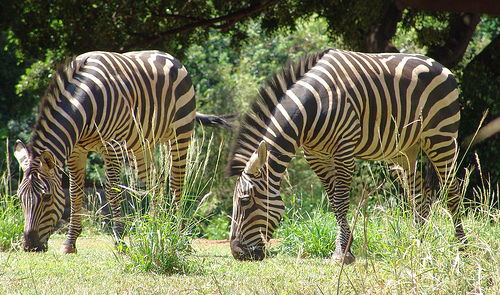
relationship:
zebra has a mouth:
[13, 48, 197, 255] [25, 241, 46, 252]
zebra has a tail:
[13, 48, 197, 255] [196, 111, 239, 129]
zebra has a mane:
[13, 48, 197, 255] [29, 52, 87, 164]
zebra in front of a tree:
[13, 48, 197, 255] [112, 3, 499, 211]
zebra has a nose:
[13, 48, 197, 255] [231, 238, 244, 259]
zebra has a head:
[13, 48, 197, 255] [231, 173, 285, 260]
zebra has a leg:
[13, 48, 197, 255] [170, 125, 192, 214]